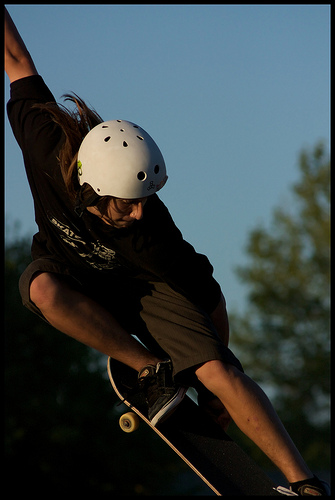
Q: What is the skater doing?
A: A trick.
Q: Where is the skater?
A: In the air.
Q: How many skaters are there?
A: One.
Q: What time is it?
A: Daytime.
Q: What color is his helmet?
A: White.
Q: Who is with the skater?
A: No one.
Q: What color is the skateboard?
A: Black.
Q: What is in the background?
A: Trees.